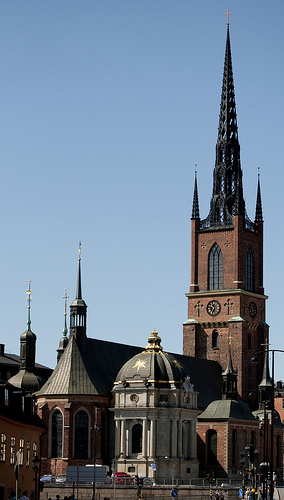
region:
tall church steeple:
[187, 3, 272, 298]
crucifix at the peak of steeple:
[223, 9, 230, 24]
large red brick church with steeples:
[2, 1, 273, 492]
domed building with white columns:
[112, 328, 196, 480]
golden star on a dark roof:
[130, 355, 150, 374]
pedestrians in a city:
[164, 486, 230, 498]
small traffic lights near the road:
[205, 473, 216, 480]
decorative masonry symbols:
[190, 297, 239, 318]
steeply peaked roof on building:
[36, 336, 100, 396]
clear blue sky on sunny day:
[22, 106, 133, 217]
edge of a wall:
[229, 433, 236, 459]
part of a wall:
[220, 424, 230, 451]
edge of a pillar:
[148, 394, 152, 450]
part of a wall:
[137, 484, 147, 489]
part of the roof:
[66, 350, 81, 383]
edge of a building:
[230, 348, 253, 383]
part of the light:
[241, 461, 245, 477]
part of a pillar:
[147, 406, 151, 448]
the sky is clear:
[52, 79, 129, 201]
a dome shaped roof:
[84, 342, 208, 404]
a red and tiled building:
[193, 236, 229, 369]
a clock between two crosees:
[180, 295, 238, 324]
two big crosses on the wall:
[190, 296, 241, 323]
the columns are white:
[136, 420, 160, 456]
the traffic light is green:
[205, 477, 221, 487]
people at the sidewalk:
[136, 484, 239, 498]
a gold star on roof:
[126, 355, 156, 381]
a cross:
[224, 9, 234, 24]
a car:
[54, 469, 68, 484]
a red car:
[113, 471, 130, 482]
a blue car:
[39, 473, 54, 484]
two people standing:
[214, 487, 229, 497]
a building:
[122, 357, 192, 462]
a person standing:
[166, 485, 178, 497]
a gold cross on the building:
[23, 275, 34, 285]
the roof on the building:
[206, 401, 233, 417]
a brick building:
[218, 430, 230, 469]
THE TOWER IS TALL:
[176, 5, 283, 421]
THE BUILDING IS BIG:
[0, 6, 280, 496]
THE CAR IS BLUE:
[36, 469, 55, 482]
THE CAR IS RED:
[106, 470, 133, 485]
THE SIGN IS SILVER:
[59, 459, 108, 483]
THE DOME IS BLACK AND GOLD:
[110, 332, 191, 390]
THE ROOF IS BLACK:
[28, 321, 241, 419]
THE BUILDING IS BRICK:
[0, 5, 282, 494]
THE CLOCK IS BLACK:
[203, 297, 225, 318]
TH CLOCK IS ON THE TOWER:
[205, 298, 221, 319]